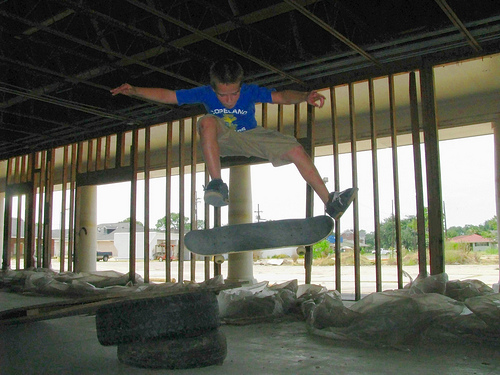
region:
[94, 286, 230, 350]
Old rubber tire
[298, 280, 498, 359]
Plastic sheeting lying on the ground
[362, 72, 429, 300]
Wall under construction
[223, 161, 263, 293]
Concrete support pillar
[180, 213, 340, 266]
Skateboard in mid air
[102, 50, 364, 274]
Young boy doing a trick on a skateboard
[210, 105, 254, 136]
Designs screen printed onto T-shirt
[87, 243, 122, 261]
Truck parked in the parking lot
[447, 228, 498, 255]
Building in the background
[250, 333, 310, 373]
Surface of concrete floor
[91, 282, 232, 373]
the tires are on the floor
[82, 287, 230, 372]
the tires are dirty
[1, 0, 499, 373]
the building is unfinished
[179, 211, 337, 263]
the skateboard is black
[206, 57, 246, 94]
the boy has short hair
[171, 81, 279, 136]
the boy is wearing a t-shirt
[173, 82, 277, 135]
the boy's t-shirt is blue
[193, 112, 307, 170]
the boy is wearing shorts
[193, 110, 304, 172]
the boy's shorts are tan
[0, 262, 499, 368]
the plastic is on the floor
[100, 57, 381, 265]
boy in catching air on skateboard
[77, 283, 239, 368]
stack of tires on floor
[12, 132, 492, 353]
empty building without walls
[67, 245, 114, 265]
blue pickup truck in parking lot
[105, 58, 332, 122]
boy wearing blue t-shirt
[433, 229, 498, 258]
building with red roof past the parking lot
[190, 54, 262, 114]
boy with short blonde hair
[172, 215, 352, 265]
skateboard with white wheels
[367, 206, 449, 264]
trees past the parking lot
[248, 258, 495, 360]
plastic tarps on floor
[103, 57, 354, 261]
a skateboarder jumping in air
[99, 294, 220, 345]
a black tire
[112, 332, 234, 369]
a black tire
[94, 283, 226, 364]
a stack of black tires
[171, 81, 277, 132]
a deep blue printed short sleeve t-shirt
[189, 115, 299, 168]
a pair of khaki shorts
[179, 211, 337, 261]
a worn grey skateboard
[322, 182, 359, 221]
a grey and white shoe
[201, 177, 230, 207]
a grey and white shoe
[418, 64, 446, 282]
a wooden stud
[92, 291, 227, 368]
Old, worn tires in a pile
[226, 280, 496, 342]
Plastic bunched by side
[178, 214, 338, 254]
Skate board in the air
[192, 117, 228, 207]
Boy's right leg in the air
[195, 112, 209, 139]
Boy's right knee is skinned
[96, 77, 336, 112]
Boy's arms are outstretched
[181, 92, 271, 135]
Boy is wearing blue shirt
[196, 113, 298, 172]
Boy is wearing khaki shorts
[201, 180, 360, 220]
Boy is wearing black shoes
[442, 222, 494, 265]
House in the background